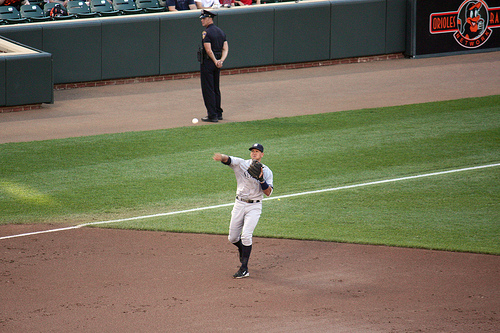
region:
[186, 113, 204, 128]
White game ball in flight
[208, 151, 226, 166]
Hand of ball player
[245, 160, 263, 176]
Gloved hand of ball player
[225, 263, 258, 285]
Feet of ball player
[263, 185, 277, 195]
Elbow of ball player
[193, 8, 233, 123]
Policeman on duty at game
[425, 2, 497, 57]
Advertisement on panel at game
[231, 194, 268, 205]
Belt for ball player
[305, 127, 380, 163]
Green grassy area on field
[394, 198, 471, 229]
Green grass on a baseball field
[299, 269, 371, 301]
Dirt on a baseball infield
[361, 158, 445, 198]
foul line on the left side of baseball field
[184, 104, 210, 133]
baseball in the air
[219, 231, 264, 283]
player wearing black socks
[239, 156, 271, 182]
player wearing a baseball glove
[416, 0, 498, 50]
team logo on sideline wall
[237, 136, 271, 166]
player wearing a black hat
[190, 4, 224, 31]
dark hat on a police officer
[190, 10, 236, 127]
police officer standing on side of field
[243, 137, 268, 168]
head of a person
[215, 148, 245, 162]
arm of a person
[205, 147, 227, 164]
hand of a person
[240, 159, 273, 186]
hand of a person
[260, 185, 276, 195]
elbow of a person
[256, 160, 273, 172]
shoulder of a person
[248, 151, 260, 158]
face of a person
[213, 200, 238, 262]
leg of a person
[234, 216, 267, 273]
leg of a person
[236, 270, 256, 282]
feet of a person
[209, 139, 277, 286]
Pitcher throwing a ball.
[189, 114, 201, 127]
Ball in midair.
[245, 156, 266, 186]
Mitt on the hand.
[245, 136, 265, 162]
Hat on the player.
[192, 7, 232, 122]
Security guard on the field.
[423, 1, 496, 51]
Emblem on the wall.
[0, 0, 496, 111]
Wall in the background.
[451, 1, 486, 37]
Bird in the emblem.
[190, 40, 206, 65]
Radio on security guard.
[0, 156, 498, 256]
White line on the field.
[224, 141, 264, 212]
grey and black shirt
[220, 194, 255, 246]
man has white pants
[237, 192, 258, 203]
man has black belt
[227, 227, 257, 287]
man has black socks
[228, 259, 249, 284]
black and white shoes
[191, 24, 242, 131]
police officer in foul ground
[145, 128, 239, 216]
green grass in outfield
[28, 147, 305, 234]
white line on foul ground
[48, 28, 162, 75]
green fence in foul ground